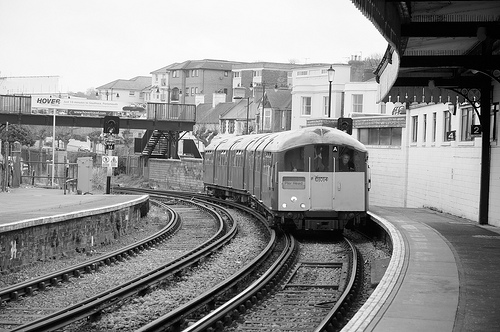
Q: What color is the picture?
A: The picture is grey.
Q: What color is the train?
A: The train is grey.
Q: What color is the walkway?
A: The walkway is grey.